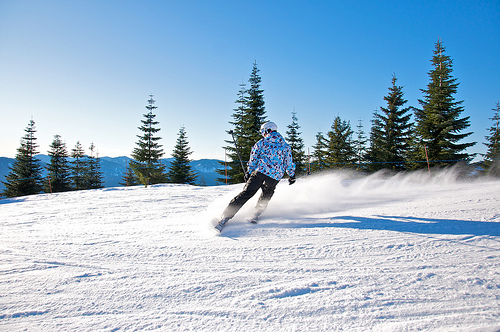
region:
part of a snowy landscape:
[392, 264, 432, 280]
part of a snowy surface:
[91, 270, 113, 302]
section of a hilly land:
[113, 162, 120, 172]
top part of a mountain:
[202, 157, 212, 162]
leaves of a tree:
[433, 80, 448, 97]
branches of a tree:
[374, 132, 389, 139]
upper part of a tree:
[431, 42, 439, 48]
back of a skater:
[261, 143, 278, 176]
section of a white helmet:
[268, 124, 274, 131]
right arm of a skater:
[288, 155, 294, 177]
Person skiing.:
[197, 101, 317, 248]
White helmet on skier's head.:
[198, 106, 321, 249]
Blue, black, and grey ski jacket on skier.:
[237, 117, 309, 195]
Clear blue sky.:
[325, 13, 497, 215]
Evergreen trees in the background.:
[159, 35, 361, 293]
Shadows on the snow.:
[208, 100, 497, 255]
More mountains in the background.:
[2, 80, 221, 243]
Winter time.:
[1, 3, 498, 284]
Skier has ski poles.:
[188, 35, 332, 262]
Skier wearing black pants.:
[205, 141, 288, 240]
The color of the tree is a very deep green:
[425, 42, 482, 179]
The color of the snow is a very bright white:
[363, 220, 420, 312]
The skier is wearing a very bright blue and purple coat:
[263, 120, 304, 190]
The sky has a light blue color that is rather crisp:
[112, 65, 134, 113]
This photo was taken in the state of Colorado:
[104, 44, 399, 304]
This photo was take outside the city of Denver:
[114, 29, 399, 305]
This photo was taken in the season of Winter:
[102, 25, 425, 323]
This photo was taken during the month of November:
[101, 24, 408, 306]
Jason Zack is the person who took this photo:
[79, 22, 432, 312]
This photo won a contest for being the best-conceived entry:
[91, 30, 368, 327]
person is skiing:
[192, 84, 353, 268]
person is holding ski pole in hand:
[217, 117, 270, 206]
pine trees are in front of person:
[95, 46, 495, 191]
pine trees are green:
[103, 73, 496, 238]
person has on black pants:
[206, 160, 300, 267]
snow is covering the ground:
[59, 183, 418, 313]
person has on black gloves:
[241, 141, 382, 234]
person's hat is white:
[215, 104, 317, 146]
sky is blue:
[189, 3, 494, 154]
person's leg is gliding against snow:
[153, 171, 328, 277]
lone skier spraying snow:
[211, 104, 312, 236]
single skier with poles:
[195, 91, 317, 266]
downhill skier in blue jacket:
[200, 95, 308, 255]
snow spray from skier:
[299, 170, 420, 247]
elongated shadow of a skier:
[284, 201, 497, 253]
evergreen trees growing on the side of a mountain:
[13, 112, 196, 182]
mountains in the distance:
[5, 130, 160, 190]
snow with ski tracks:
[98, 225, 262, 320]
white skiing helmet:
[255, 119, 280, 139]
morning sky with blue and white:
[21, 62, 133, 144]